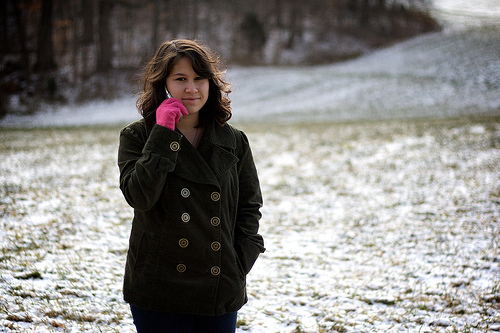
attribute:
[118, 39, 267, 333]
woman — young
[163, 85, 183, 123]
phone — cellular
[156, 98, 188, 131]
glove — pink, bright pink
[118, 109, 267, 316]
coat — brown, for winter, dark, dark brown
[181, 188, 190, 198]
button — brassy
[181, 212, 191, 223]
button — brassy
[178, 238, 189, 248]
button — brassy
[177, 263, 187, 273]
button — brassy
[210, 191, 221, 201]
button — brassy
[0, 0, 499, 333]
grass — hilly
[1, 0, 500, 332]
snow — fresh, thin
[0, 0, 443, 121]
wooded area — dense, bare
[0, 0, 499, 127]
hillside — rolling, distant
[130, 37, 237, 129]
hair — brown, shoulder length, dark, curly, wavy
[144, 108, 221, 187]
right lapel — wide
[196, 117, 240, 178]
left lapel — wide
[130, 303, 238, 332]
jeans — blue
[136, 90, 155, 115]
curl — brown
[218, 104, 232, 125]
curl — brown